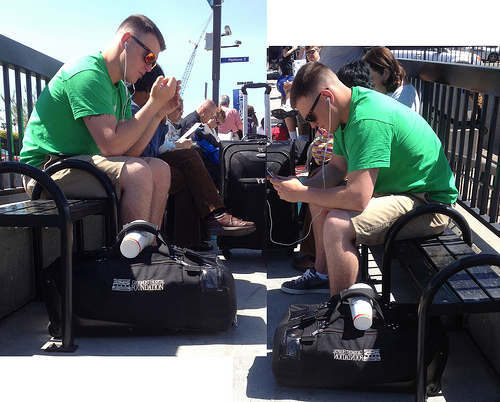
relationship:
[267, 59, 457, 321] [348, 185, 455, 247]
man has on shorts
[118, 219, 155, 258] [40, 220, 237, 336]
cup on bag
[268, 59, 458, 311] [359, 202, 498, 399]
man sitting on a bench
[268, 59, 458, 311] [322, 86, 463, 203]
man wearing shirt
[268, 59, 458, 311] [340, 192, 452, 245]
man wearing shorts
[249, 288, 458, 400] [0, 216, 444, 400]
black bag on ground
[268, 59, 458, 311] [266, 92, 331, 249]
man wearing headphones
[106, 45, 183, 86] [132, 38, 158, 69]
man with sunglasses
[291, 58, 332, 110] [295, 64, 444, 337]
short hair on man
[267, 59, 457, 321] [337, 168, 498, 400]
man sitting on bench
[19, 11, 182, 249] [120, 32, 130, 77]
man has earbuds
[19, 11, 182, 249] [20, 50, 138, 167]
man wearing shirt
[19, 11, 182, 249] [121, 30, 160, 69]
man wearing sunglasses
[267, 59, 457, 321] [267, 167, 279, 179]
man holding cell phone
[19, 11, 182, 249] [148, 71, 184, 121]
man looking at nails